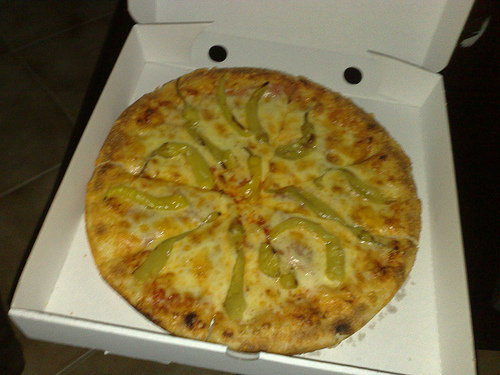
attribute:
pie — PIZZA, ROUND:
[124, 48, 427, 366]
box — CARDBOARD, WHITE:
[382, 330, 440, 360]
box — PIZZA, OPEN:
[129, 57, 169, 87]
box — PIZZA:
[403, 310, 447, 355]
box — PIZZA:
[395, 308, 441, 354]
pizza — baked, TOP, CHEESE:
[77, 54, 424, 372]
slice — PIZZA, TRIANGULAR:
[243, 230, 328, 353]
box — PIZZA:
[377, 301, 439, 365]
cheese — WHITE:
[296, 152, 320, 176]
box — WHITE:
[368, 316, 435, 358]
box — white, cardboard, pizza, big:
[9, 0, 485, 373]